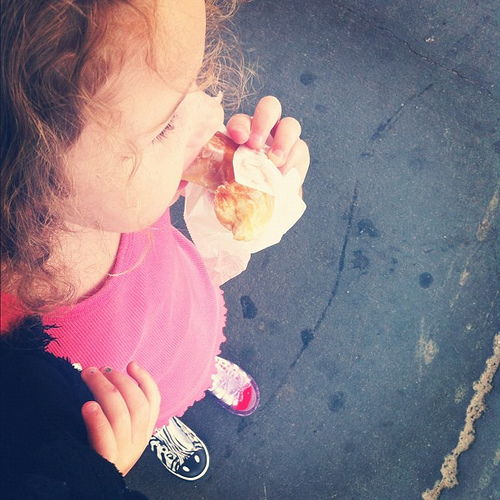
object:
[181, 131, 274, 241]
donut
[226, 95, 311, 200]
hand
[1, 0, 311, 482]
girl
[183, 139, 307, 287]
wrapper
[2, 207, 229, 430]
shirt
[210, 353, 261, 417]
shoe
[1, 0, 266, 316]
hair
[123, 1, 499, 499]
concrete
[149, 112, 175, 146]
eye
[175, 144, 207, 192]
mouth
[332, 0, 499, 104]
crack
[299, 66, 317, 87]
spot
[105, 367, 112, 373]
paint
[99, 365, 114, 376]
fingernail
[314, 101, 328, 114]
spot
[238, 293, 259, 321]
spot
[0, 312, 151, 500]
stuffed toy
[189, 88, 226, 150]
nose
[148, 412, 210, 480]
shoes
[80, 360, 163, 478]
right hand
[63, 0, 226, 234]
face